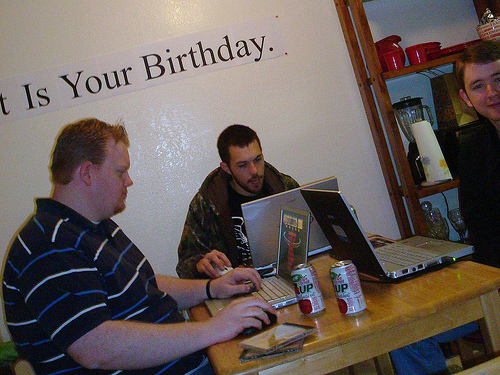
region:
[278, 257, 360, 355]
two cans are visible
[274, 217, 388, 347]
two cans are visible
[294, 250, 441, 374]
two cans are visible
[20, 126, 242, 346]
man sitting at a table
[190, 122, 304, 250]
man sitting at a table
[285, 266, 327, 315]
soda can on the table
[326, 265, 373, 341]
soda can on the table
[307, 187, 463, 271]
laptop on the table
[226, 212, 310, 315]
laptop on the table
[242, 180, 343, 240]
laptop on the table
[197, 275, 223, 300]
bracelet on man's wrist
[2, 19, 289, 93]
sign on the wall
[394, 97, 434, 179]
blender on a shelf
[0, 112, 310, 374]
Two men sitting at table working on computers.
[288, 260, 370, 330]
Two beverage cans sitting on table.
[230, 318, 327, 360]
Two disk sitting on table.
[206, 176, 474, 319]
Three laptop computers sitting on table.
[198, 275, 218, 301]
Man wearing watch on left wrist.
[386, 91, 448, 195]
Blender sitting on shelf.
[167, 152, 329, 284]
Man dressed in camouflage like jacket.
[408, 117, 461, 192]
Towel paper sitting in front of blender on shelf.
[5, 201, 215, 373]
Man dressed in striped shirt.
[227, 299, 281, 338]
Man holding black computer mouse in hand.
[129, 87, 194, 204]
the wall is shiny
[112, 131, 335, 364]
the wall is shiny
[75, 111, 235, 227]
the wall is shiny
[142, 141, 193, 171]
the wall is shiny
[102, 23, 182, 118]
the wall is shiny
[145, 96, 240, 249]
the wall is shiny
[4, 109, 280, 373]
the man on the laptop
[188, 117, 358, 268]
the man on the laptop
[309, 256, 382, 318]
the can of soda on the table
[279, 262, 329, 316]
the can of soda on the table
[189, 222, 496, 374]
the table is wooden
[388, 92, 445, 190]
the blender is on the shelf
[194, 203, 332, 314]
the laptop is on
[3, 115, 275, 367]
the man is fat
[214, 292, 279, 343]
the hand on the mouse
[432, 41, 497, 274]
the man is smiling